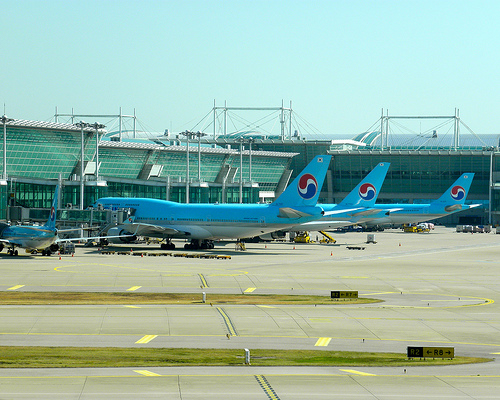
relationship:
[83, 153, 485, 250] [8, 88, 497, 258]
aircraft parked at airport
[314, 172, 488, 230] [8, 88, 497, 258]
aircraft parked at airport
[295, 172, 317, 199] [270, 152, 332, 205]
logo on vertical stabilizer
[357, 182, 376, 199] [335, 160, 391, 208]
logo on vertical stabilizer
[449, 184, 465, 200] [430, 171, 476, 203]
logo on vertical stabilizer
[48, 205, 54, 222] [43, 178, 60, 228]
logo on vertical stabilizer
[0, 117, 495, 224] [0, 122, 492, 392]
building at airport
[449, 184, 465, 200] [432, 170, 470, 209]
logo on stabilizer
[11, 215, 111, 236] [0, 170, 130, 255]
stabilizer on plane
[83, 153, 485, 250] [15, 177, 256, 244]
aircraft an gates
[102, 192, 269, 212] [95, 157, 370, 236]
top of plane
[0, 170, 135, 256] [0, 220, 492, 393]
plane in parking lot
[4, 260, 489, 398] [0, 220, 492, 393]
lines on parking lot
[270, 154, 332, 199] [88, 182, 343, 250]
tail on plane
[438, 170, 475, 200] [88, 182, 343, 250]
tail on plane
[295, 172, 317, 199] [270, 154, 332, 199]
logo on tail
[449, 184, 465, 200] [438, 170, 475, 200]
logo on tail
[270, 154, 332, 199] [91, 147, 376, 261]
tail of plane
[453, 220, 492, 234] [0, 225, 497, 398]
carts on pavement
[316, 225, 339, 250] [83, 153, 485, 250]
stairs to aircraft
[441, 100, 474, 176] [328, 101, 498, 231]
poles attached to building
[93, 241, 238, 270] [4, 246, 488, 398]
carriers on runway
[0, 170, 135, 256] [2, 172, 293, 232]
plane at terminal